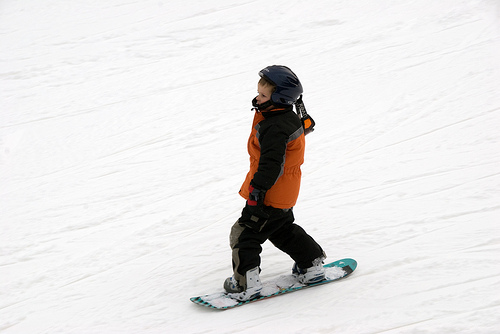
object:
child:
[222, 65, 324, 301]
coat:
[239, 109, 303, 209]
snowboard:
[190, 258, 356, 310]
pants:
[229, 201, 325, 288]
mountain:
[0, 0, 500, 334]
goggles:
[295, 95, 316, 134]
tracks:
[301, 170, 457, 217]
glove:
[246, 185, 269, 218]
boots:
[224, 254, 325, 301]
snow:
[204, 294, 236, 306]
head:
[251, 65, 302, 111]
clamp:
[306, 276, 327, 285]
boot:
[293, 264, 300, 276]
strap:
[251, 96, 272, 111]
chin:
[253, 104, 267, 111]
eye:
[261, 94, 266, 97]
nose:
[256, 95, 261, 100]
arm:
[249, 129, 285, 199]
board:
[190, 258, 356, 306]